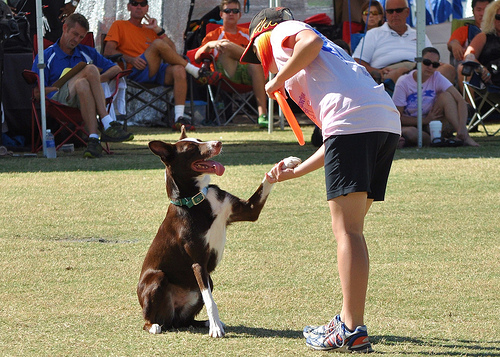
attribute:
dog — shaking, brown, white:
[136, 125, 301, 339]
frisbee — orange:
[272, 86, 309, 149]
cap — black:
[238, 7, 291, 66]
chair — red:
[22, 33, 130, 155]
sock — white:
[174, 104, 186, 120]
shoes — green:
[258, 113, 275, 129]